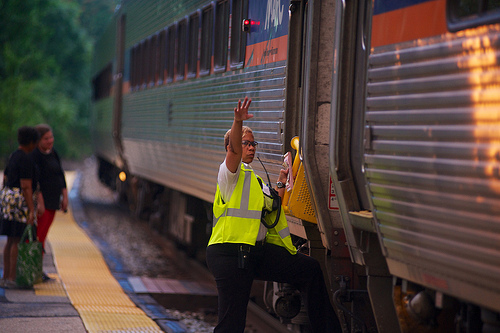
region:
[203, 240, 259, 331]
Woman is wearing pants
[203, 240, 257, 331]
Woman is wearing black pants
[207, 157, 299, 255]
Woman is wearing a vest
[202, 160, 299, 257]
Woman is wearing a green vest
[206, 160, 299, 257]
Woman is wearing a reflective vest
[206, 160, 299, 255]
Woman is wearing a reflective green vest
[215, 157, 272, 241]
Woman is wearing a shirt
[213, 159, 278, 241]
Woman is wearing a white shirt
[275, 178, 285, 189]
Woman is wearing a watch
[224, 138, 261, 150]
Woman is wearing glasses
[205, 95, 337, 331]
a train worker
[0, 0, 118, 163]
a group of large green trees in the background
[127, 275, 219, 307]
a walkway leading to the train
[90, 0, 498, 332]
a metallic passenger train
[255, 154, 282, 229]
the worker's walkie talkie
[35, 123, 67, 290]
a woman in red pants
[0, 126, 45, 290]
a woman with a green bag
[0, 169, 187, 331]
the train station platform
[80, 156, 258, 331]
an area of gravel next to the tracks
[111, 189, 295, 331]
one of the train track rails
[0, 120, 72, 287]
two women standing on platform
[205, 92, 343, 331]
woman wearing yellow vest getting on train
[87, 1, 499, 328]
silver passenger train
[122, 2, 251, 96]
windows on train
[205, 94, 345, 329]
woman with right arm raised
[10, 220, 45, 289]
green bag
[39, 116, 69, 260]
woman wearing black shirt and red pants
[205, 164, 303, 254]
neon yellow safety vest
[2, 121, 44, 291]
woman wearing black holding green bag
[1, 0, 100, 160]
green trees in the distance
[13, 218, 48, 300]
A green hand bag with white patches being held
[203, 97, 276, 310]
A woman with hair cut short raising her hand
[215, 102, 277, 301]
A woman wearing a white shirt and bright neon yellow vest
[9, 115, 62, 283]
Two women standing together on the platform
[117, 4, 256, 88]
Row of black windows in the side of a gray metal train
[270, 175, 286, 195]
Gray metal watch on a wrist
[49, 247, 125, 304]
Yellow painted part of the platform with bumps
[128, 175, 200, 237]
Black wheels of a train underneath a silver colored car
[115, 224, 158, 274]
Gray gravel of rocks and pebbles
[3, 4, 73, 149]
Thick dark green trees standing tall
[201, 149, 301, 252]
yellow and silver reflective vest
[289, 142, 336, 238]
yellow folded train stairs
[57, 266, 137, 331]
yellow painted pathway on sidewalk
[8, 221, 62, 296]
green and white woman's luggage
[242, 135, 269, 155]
glasses on woman's face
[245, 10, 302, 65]
orange and blue train advertising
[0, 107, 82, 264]
two women awaiting the train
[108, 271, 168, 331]
blue painted line on sidewalk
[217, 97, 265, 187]
woman's right outstretched hand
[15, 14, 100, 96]
green leafy tree in background